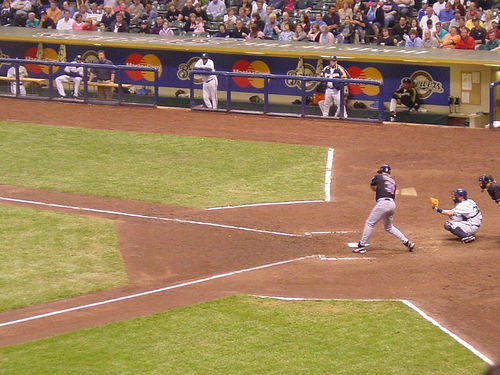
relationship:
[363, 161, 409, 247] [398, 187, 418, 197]
batter swinging a bat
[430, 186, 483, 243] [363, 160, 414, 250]
catcher behind batter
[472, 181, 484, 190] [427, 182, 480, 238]
referee behind catcher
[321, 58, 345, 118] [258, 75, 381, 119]
player standing behind railing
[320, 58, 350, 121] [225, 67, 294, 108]
player standing behind railing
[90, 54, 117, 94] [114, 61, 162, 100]
man standing behind railing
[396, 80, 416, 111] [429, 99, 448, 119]
player sitting on bench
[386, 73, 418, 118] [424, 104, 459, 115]
player sitting on bench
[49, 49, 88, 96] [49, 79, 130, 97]
player sitting on bench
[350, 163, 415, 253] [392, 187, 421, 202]
player swings bat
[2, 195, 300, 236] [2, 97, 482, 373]
line mark playing field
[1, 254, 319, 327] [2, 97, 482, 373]
line mark playing field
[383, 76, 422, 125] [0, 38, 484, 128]
player in dugout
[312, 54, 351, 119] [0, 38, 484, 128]
player in dugout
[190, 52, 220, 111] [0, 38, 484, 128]
player in dugout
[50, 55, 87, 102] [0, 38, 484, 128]
player in dugout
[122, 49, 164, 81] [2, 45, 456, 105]
logo on wall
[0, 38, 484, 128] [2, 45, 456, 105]
dugout has wall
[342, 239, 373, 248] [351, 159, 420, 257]
home plate under batter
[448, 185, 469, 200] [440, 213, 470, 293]
purple hat on player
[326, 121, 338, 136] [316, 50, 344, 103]
purple hat on player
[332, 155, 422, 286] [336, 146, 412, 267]
person hitting a baseball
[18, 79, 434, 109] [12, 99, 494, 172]
baseball players watching from dugout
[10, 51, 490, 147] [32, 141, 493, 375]
crowd in stands watching a baseball game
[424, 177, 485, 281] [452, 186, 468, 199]
man wearing a helmet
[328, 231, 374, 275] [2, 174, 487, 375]
home plate on a baseball field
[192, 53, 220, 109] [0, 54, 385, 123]
player on fence